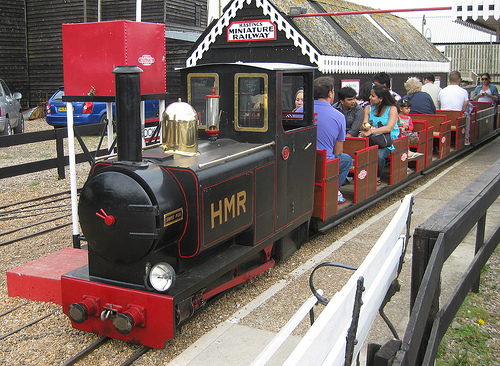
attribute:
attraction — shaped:
[55, 47, 499, 347]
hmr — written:
[202, 190, 252, 230]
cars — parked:
[0, 72, 163, 141]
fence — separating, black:
[0, 104, 175, 191]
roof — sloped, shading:
[183, 0, 453, 66]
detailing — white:
[316, 53, 455, 74]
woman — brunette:
[364, 80, 402, 187]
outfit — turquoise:
[365, 102, 399, 140]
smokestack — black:
[108, 62, 153, 162]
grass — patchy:
[428, 236, 497, 364]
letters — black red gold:
[193, 175, 273, 246]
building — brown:
[184, 0, 447, 128]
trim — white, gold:
[186, 0, 455, 75]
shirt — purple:
[290, 101, 349, 155]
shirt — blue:
[366, 100, 404, 143]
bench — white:
[232, 191, 415, 365]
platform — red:
[4, 234, 110, 312]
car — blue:
[42, 83, 176, 131]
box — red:
[58, 17, 176, 101]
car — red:
[310, 117, 413, 226]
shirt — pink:
[396, 111, 413, 132]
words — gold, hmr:
[201, 187, 255, 229]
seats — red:
[312, 96, 500, 226]